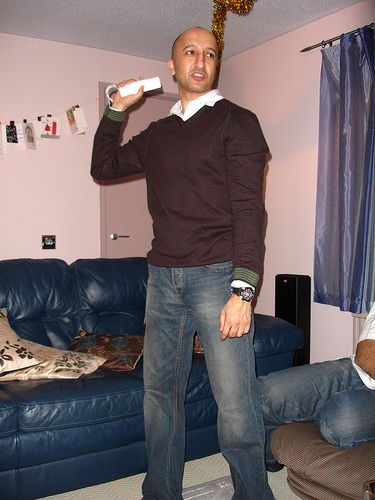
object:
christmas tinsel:
[210, 0, 258, 90]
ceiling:
[0, 0, 368, 66]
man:
[89, 25, 277, 500]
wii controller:
[105, 75, 163, 113]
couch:
[0, 255, 306, 500]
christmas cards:
[65, 102, 90, 137]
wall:
[0, 31, 182, 265]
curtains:
[359, 121, 374, 135]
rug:
[181, 473, 236, 499]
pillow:
[64, 325, 145, 372]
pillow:
[0, 338, 109, 380]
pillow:
[0, 305, 41, 375]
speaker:
[274, 273, 313, 369]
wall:
[217, 0, 375, 366]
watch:
[230, 285, 255, 304]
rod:
[299, 22, 375, 55]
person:
[257, 299, 375, 450]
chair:
[269, 418, 374, 500]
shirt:
[88, 87, 271, 291]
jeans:
[140, 259, 277, 499]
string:
[0, 97, 98, 127]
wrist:
[231, 282, 255, 302]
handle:
[109, 233, 131, 241]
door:
[99, 80, 182, 259]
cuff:
[230, 266, 261, 288]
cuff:
[103, 103, 127, 122]